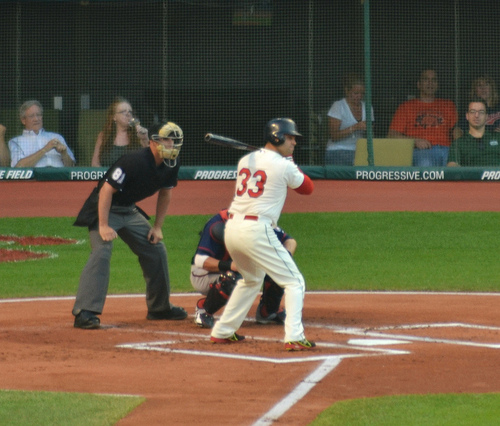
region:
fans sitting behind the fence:
[316, 62, 498, 177]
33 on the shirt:
[228, 160, 275, 207]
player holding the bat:
[200, 108, 316, 356]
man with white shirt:
[5, 93, 74, 177]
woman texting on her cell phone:
[320, 65, 377, 156]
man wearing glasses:
[448, 89, 498, 167]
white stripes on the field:
[339, 321, 416, 360]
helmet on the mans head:
[261, 109, 301, 140]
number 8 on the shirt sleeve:
[107, 161, 132, 186]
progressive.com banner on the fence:
[349, 168, 451, 183]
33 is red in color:
[221, 168, 277, 209]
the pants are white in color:
[221, 232, 304, 342]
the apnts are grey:
[81, 233, 183, 305]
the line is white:
[271, 366, 331, 423]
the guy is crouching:
[198, 205, 268, 325]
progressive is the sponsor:
[348, 167, 440, 187]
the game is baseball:
[4, 102, 494, 423]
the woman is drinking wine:
[97, 105, 150, 147]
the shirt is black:
[95, 153, 190, 208]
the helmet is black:
[266, 115, 301, 140]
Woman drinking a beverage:
[92, 98, 152, 167]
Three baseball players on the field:
[64, 112, 321, 352]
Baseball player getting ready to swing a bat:
[201, 116, 318, 351]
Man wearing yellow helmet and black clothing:
[71, 118, 188, 331]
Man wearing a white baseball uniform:
[207, 118, 317, 354]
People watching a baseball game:
[326, 68, 497, 183]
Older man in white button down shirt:
[8, 99, 76, 168]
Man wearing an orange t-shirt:
[387, 65, 459, 167]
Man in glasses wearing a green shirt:
[446, 93, 498, 165]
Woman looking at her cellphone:
[320, 77, 375, 167]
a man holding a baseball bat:
[198, 101, 343, 208]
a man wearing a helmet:
[260, 108, 309, 158]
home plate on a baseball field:
[310, 314, 435, 393]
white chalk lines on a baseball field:
[328, 296, 495, 424]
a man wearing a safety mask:
[131, 115, 191, 185]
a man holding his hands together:
[28, 139, 76, 156]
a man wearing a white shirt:
[3, 105, 67, 182]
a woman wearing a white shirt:
[323, 70, 370, 156]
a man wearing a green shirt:
[458, 87, 493, 182]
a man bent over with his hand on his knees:
[77, 116, 183, 279]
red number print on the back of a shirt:
[235, 166, 270, 198]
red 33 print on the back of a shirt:
[231, 167, 267, 199]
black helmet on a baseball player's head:
[263, 115, 303, 146]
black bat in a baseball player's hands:
[201, 131, 263, 155]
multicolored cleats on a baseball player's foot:
[282, 338, 317, 349]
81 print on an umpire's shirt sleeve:
[107, 168, 127, 185]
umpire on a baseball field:
[69, 118, 189, 329]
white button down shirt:
[7, 128, 73, 164]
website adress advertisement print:
[351, 168, 447, 180]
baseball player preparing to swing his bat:
[203, 115, 318, 352]